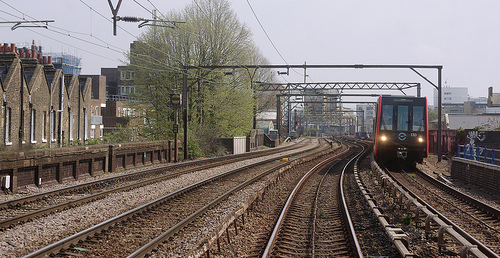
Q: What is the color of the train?
A: Red and black.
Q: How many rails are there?
A: Four.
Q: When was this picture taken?
A: Daytime.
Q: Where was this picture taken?
A: Dockland railway station.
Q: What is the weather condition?
A: Cloudy.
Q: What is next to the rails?
A: Houses.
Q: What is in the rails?
A: Dlr train.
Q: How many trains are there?
A: One.